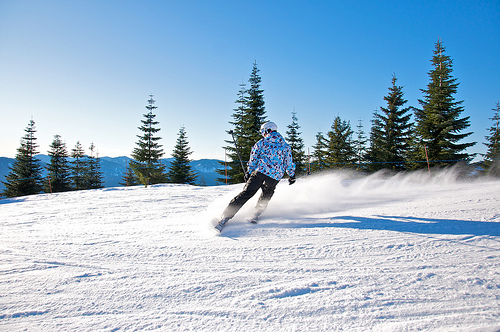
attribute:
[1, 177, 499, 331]
snow — white, heavily tracked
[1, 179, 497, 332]
ground — snowy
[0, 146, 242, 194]
hills — together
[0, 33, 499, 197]
pine trees — green, growing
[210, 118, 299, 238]
skiier — skiing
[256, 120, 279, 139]
helmet — white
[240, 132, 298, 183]
jacket — bright blue, purple, blue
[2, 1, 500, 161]
sky — blue, crisp, white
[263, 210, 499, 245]
shadow — long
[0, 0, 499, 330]
photo — in colorado, near denver, in winter, by jason zack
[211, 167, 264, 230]
leg — gliding